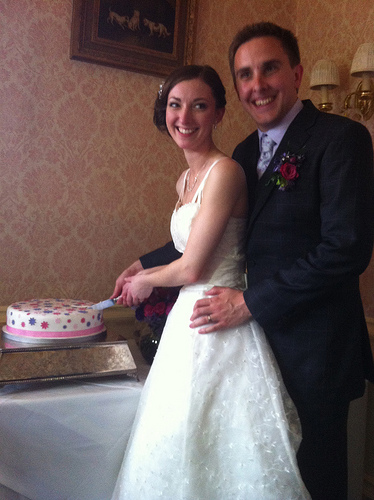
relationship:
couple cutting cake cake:
[153, 20, 303, 150] [2, 296, 108, 347]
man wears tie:
[110, 21, 374, 500] [233, 114, 272, 154]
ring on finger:
[205, 313, 214, 322] [187, 308, 223, 329]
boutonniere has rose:
[264, 149, 305, 192] [277, 157, 298, 182]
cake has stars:
[2, 298, 107, 341] [23, 307, 53, 330]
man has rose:
[223, 21, 371, 498] [277, 156, 297, 181]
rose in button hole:
[277, 156, 297, 181] [271, 164, 293, 194]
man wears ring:
[223, 21, 371, 498] [207, 315, 211, 323]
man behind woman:
[110, 21, 374, 500] [113, 62, 309, 495]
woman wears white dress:
[113, 62, 309, 495] [114, 154, 304, 491]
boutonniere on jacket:
[261, 140, 308, 193] [136, 97, 371, 408]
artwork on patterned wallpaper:
[68, 0, 188, 80] [1, 0, 190, 305]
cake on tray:
[5, 298, 105, 334] [4, 327, 126, 349]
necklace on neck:
[183, 152, 211, 193] [175, 143, 223, 170]